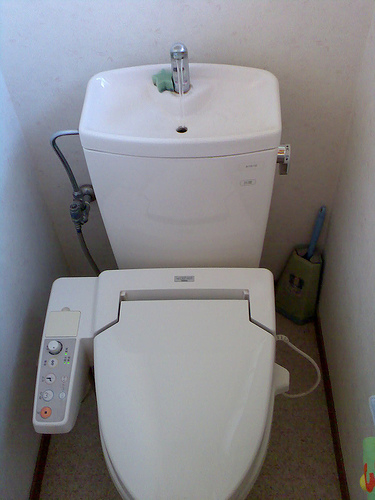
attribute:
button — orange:
[39, 407, 56, 420]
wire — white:
[273, 332, 322, 398]